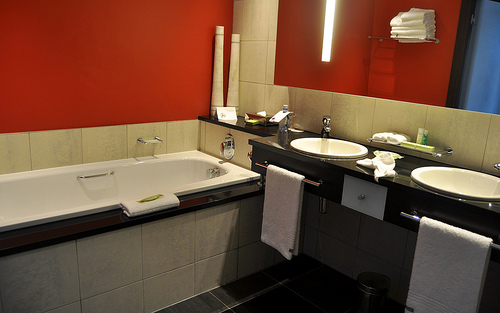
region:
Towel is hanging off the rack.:
[241, 148, 319, 242]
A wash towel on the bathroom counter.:
[362, 142, 412, 190]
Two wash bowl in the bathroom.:
[294, 119, 490, 202]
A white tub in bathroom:
[16, 172, 243, 215]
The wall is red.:
[45, 27, 193, 102]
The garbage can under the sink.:
[316, 263, 397, 309]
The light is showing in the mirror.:
[311, 5, 360, 64]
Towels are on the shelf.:
[386, 13, 434, 51]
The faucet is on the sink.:
[298, 110, 337, 142]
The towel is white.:
[247, 151, 302, 266]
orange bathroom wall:
[0, 2, 232, 132]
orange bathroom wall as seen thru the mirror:
[273, 0, 463, 109]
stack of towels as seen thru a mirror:
[387, 7, 437, 44]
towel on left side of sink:
[255, 161, 305, 261]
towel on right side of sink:
[404, 212, 494, 312]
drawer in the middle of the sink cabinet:
[334, 167, 389, 227]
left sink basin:
[287, 134, 370, 161]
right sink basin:
[409, 164, 497, 201]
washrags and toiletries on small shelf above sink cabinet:
[370, 125, 450, 158]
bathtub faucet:
[215, 131, 234, 160]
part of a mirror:
[440, 54, 455, 66]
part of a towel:
[416, 285, 420, 294]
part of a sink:
[132, 165, 152, 185]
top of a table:
[339, 168, 356, 185]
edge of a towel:
[288, 193, 293, 238]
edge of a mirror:
[339, 88, 356, 98]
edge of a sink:
[146, 209, 159, 221]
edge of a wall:
[238, 72, 255, 87]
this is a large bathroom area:
[12, 14, 498, 298]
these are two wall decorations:
[201, 22, 254, 132]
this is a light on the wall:
[314, 0, 348, 68]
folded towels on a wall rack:
[380, 11, 445, 58]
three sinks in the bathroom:
[62, 94, 497, 232]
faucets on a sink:
[270, 96, 349, 138]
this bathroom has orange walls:
[5, 8, 232, 126]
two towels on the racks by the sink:
[256, 153, 498, 306]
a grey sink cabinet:
[10, 182, 315, 301]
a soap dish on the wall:
[131, 131, 170, 152]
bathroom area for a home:
[11, 18, 473, 303]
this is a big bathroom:
[14, 88, 491, 268]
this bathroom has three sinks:
[67, 88, 497, 225]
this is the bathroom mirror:
[261, 3, 491, 129]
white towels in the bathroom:
[241, 156, 483, 309]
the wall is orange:
[4, 5, 225, 110]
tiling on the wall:
[5, 124, 275, 176]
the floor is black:
[163, 234, 401, 311]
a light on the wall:
[312, 2, 337, 76]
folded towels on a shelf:
[380, 3, 450, 48]